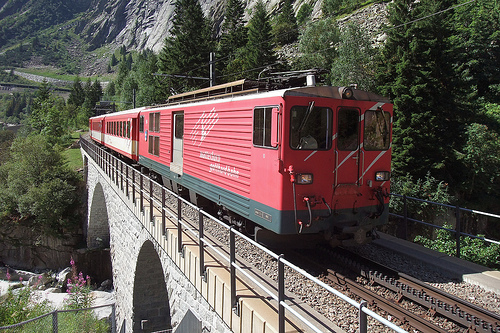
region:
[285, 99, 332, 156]
Window of a train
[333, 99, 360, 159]
Window of a train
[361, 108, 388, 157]
Window of a train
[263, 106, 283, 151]
Window of a train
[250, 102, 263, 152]
Window of a train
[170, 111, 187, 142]
Window of a train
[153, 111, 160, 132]
Window of a train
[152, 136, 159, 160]
Window of a train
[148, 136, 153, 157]
Window of a train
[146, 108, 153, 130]
Window of a train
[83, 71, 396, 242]
Red passenger train and engine.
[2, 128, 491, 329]
Stone bridge over gorge.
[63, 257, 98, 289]
Purple flowers on end of green branches.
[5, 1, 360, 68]
High, steep gray mountains.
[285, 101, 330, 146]
Window on front of train.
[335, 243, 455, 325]
Metal train tracks on gravel bed.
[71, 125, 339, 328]
Metal railing on train bridge.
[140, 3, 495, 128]
Tall, green pine trees.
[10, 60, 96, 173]
Green grass in the valley.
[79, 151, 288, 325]
Gray stone railway bridge.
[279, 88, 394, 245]
a front of a red train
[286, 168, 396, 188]
head lights on a train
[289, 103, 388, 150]
front windows on a train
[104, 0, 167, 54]
a rocky hill side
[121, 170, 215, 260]
a gray metal railing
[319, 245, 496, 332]
a set of rail road tracks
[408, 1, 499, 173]
leafy green trees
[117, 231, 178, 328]
a gray stone archway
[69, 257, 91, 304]
a pink flower weed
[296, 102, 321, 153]
a windshield wiper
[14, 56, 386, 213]
the train is red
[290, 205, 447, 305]
the train is on tracks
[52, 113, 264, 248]
the train is on a bridge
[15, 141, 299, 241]
tracks on a bridge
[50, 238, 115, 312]
pink flowers under the bridge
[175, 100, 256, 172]
the text is white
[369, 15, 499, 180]
Trees next to the train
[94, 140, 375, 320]
the railing is metal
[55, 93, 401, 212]
the train is moving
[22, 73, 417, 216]
the train has 3 cars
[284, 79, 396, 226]
the front of a train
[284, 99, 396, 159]
the window of a red train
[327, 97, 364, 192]
the back door of a red train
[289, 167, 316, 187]
the headlights of a red train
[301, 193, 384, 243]
the bumper of a red train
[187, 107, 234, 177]
the logo of a red train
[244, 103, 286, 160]
the side window of a red train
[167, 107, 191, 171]
the side door of a red train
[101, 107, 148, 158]
a car of a red train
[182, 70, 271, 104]
the ceiling of a red train